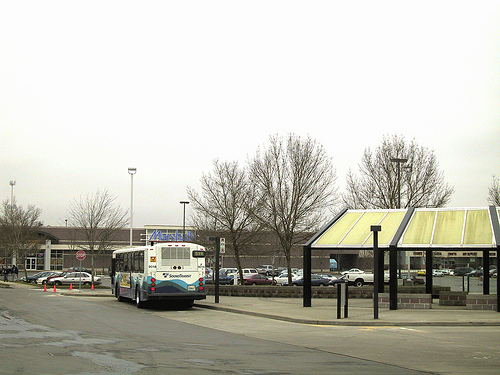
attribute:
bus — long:
[105, 238, 210, 311]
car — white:
[39, 259, 101, 306]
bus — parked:
[111, 239, 208, 314]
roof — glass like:
[307, 189, 498, 265]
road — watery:
[26, 307, 134, 369]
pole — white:
[125, 165, 140, 245]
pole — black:
[363, 210, 388, 303]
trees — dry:
[0, 135, 499, 282]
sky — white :
[149, 37, 469, 112]